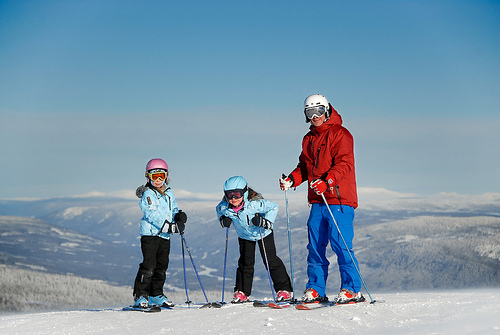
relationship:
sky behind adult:
[0, 0, 500, 200] [132, 94, 360, 309]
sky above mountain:
[10, 12, 483, 145] [0, 188, 500, 335]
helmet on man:
[305, 95, 329, 114] [278, 94, 361, 301]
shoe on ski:
[130, 295, 157, 309] [117, 298, 172, 316]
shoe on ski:
[146, 293, 167, 307] [117, 298, 172, 316]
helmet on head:
[145, 158, 168, 183] [140, 155, 172, 195]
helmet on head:
[304, 94, 329, 124] [294, 94, 334, 128]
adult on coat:
[277, 95, 357, 304] [287, 105, 357, 209]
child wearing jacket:
[215, 177, 293, 303] [209, 195, 284, 240]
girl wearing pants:
[132, 158, 186, 307] [134, 158, 176, 308]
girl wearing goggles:
[132, 158, 186, 307] [145, 166, 171, 187]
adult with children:
[134, 90, 364, 307] [129, 157, 290, 309]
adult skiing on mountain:
[134, 90, 364, 307] [0, 182, 497, 285]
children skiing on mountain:
[129, 157, 290, 309] [0, 182, 497, 285]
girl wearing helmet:
[96, 152, 196, 317] [141, 152, 168, 188]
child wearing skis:
[215, 177, 293, 303] [204, 291, 294, 310]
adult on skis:
[271, 89, 409, 277] [255, 283, 390, 324]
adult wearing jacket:
[271, 89, 409, 277] [299, 114, 403, 221]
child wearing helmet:
[215, 177, 293, 303] [185, 173, 307, 197]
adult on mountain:
[132, 94, 360, 309] [16, 263, 497, 333]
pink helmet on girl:
[143, 159, 169, 174] [132, 159, 185, 306]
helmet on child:
[222, 175, 247, 192] [215, 177, 292, 304]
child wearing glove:
[215, 177, 293, 303] [253, 216, 269, 227]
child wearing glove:
[215, 177, 293, 303] [218, 213, 234, 229]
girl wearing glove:
[132, 158, 186, 307] [174, 210, 189, 233]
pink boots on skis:
[226, 282, 296, 306] [202, 290, 300, 311]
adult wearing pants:
[277, 95, 357, 304] [300, 197, 366, 298]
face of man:
[307, 106, 327, 131] [284, 92, 363, 306]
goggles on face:
[302, 104, 329, 120] [307, 106, 327, 131]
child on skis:
[215, 177, 293, 303] [198, 292, 308, 309]